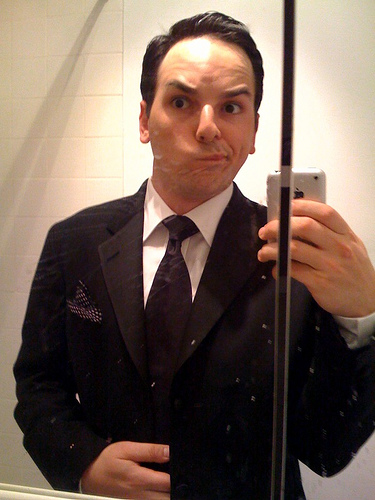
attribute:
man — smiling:
[96, 41, 295, 335]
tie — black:
[158, 216, 204, 320]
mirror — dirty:
[238, 267, 277, 377]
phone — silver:
[269, 156, 324, 209]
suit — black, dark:
[82, 221, 294, 438]